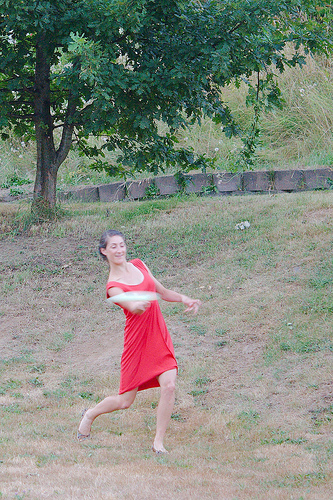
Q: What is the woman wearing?
A: Dress.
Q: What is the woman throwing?
A: Frisbee.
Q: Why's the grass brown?
A: No water.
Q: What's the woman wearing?
A: Dress.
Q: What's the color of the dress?
A: Red.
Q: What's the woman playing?
A: Frisbee.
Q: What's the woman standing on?
A: Grass.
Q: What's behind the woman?
A: Tree.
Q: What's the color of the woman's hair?
A: Brown.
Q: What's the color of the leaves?
A: Green.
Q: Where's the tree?
A: Background.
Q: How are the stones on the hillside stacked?
A: Side by side.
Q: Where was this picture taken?
A: A field.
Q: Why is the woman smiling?
A: She's having fun.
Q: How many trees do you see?
A: One.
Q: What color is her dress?
A: Red.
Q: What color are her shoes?
A: Brown.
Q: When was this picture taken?
A: Daytime.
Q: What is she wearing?
A: Dress.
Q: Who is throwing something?
A: Woman.